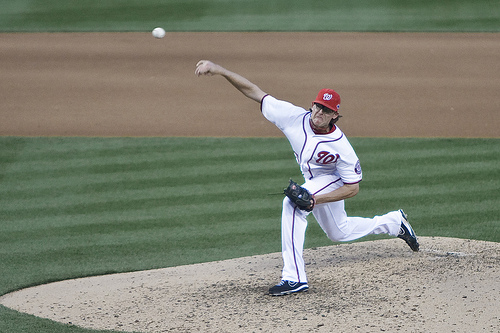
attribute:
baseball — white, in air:
[148, 22, 168, 42]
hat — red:
[312, 87, 345, 113]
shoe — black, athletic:
[391, 207, 426, 249]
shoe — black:
[267, 278, 310, 296]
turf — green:
[19, 140, 263, 252]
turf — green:
[205, 2, 498, 34]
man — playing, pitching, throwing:
[193, 54, 422, 297]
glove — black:
[282, 177, 316, 216]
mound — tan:
[338, 245, 498, 328]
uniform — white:
[264, 122, 391, 278]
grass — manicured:
[66, 148, 233, 238]